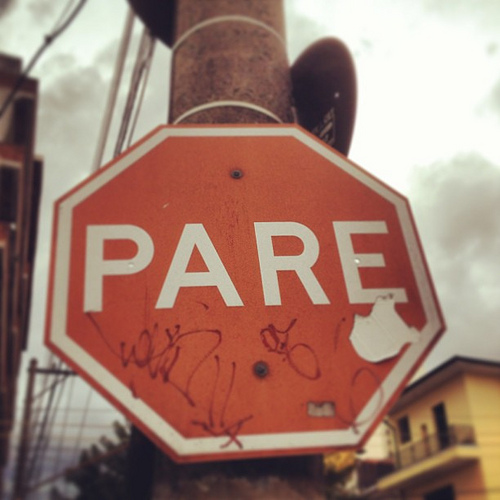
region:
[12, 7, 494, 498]
Exterior, closeup in residential area.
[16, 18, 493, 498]
Close-angled shot of sign, on gloomy day.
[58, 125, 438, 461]
Red octagon with white bordering and letters.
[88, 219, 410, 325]
"Stop" in Spanish, shows non-North American locality.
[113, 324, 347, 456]
Illegible, purple scribble-graffiti, on stop sign.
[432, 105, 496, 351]
Milky-white sky with thunderous-looking grey cloud banks.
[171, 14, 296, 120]
Rusty-brown pole with circling white details.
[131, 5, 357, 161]
Sides of second and third signs, showing.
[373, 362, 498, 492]
Yellow building with darkened doors, windows and terrace.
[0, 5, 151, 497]
Side of tall red building shown, as well as electrical pole and wires.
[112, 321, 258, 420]
graffiti on the stop sign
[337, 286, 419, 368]
a white spot on the sign where the red peeled off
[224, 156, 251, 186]
the top screw holding the sign on the post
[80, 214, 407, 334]
the word PARE on the sign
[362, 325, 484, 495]
the yellow building with a balcony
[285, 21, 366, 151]
a round sign hanging on the pole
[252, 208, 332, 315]
the letter R on the sign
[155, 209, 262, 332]
the letter A on the sign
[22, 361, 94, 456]
power lines in the distance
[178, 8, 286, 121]
straps that are holding the sign on the pole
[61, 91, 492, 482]
The sign says Pare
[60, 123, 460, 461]
The sign is red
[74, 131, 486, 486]
The sign has graffiti on it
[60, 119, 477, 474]
The sign is attached to a pole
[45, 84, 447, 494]
The word Pare is written in white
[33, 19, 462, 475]
There are power lines above the sign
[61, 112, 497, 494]
The sky is cloudy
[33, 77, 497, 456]
There is a house to the left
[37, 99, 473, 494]
The sign is octaganol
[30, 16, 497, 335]
The clouds are gray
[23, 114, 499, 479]
The red sign says "Pare"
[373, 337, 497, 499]
Tan building is in the background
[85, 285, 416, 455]
Sign has black writing on it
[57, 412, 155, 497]
Tree is in the background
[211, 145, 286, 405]
Black nails are keeping the sign in place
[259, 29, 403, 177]
The back of the sign is on the street pole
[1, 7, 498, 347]
The sky is gray and cloudy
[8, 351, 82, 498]
Wooden street pole is in the background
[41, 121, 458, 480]
Red sign has a white line around its shape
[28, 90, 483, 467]
Sign is in the shape of a octagon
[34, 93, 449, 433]
red and white stop sign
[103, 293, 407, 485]
graffiti on street sign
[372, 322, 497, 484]
yellow house with black trim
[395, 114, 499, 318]
gray cloudy skies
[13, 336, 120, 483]
power and phone lines attaches to tops of poles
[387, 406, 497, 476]
black balcony railing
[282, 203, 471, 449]
paint peeling on street sign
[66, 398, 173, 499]
large trees at a distance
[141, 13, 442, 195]
sign attached to pole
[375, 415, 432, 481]
black down spout on yellow building